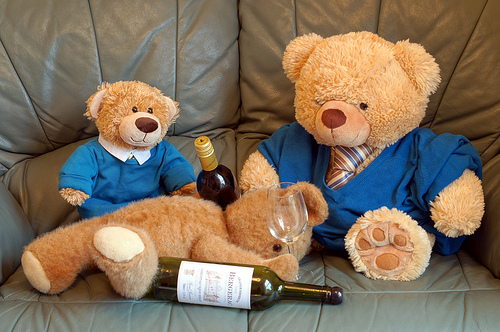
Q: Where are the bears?
A: On the couch.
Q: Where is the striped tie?
A: On the right bear.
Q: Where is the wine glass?
A: In the front bears paw.